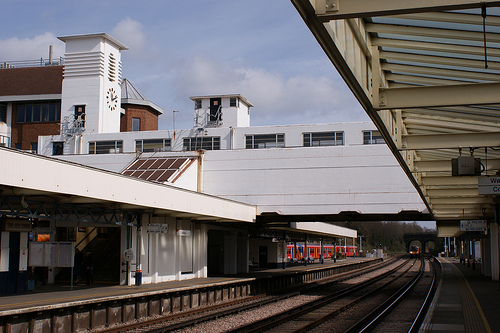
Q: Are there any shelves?
A: No, there are no shelves.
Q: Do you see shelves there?
A: No, there are no shelves.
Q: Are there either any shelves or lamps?
A: No, there are no shelves or lamps.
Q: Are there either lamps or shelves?
A: No, there are no shelves or lamps.